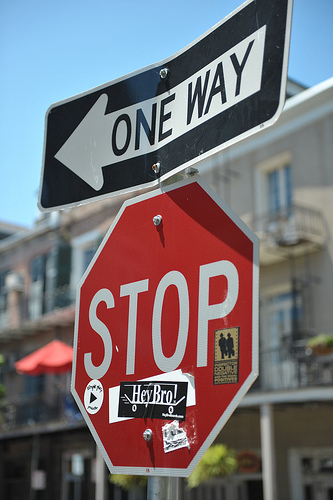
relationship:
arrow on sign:
[56, 98, 281, 163] [26, 28, 314, 211]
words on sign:
[119, 112, 257, 127] [26, 28, 314, 211]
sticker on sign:
[112, 377, 193, 417] [60, 198, 265, 427]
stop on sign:
[81, 259, 238, 381] [60, 198, 265, 427]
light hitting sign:
[132, 222, 146, 243] [60, 198, 265, 427]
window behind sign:
[255, 164, 313, 250] [60, 198, 265, 427]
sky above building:
[162, 23, 205, 35] [300, 91, 332, 139]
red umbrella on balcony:
[15, 337, 88, 373] [43, 402, 82, 429]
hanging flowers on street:
[210, 443, 256, 485] [280, 490, 288, 498]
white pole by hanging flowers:
[260, 419, 283, 455] [210, 443, 256, 485]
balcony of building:
[43, 402, 82, 429] [300, 91, 332, 139]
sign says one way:
[26, 28, 314, 211] [117, 108, 249, 124]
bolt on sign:
[146, 210, 188, 231] [60, 198, 265, 427]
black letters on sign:
[223, 51, 248, 75] [26, 28, 314, 211]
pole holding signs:
[145, 475, 179, 492] [60, 198, 265, 427]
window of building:
[255, 164, 313, 250] [300, 91, 332, 139]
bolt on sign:
[146, 210, 188, 231] [26, 28, 314, 211]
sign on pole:
[35, 0, 293, 211] [145, 475, 179, 492]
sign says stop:
[60, 198, 265, 427] [119, 318, 172, 337]